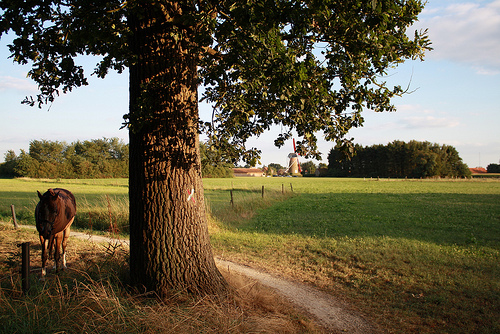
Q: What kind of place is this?
A: It is a field.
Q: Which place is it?
A: It is a field.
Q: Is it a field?
A: Yes, it is a field.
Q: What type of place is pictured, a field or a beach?
A: It is a field.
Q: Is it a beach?
A: No, it is a field.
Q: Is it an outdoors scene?
A: Yes, it is outdoors.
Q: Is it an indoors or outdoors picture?
A: It is outdoors.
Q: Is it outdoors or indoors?
A: It is outdoors.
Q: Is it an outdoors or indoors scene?
A: It is outdoors.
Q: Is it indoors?
A: No, it is outdoors.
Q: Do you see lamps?
A: No, there are no lamps.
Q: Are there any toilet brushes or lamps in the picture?
A: No, there are no lamps or toilet brushes.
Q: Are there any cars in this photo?
A: No, there are no cars.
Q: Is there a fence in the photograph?
A: Yes, there is a fence.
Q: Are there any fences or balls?
A: Yes, there is a fence.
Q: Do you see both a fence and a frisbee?
A: No, there is a fence but no frisbees.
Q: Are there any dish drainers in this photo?
A: No, there are no dish drainers.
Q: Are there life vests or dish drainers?
A: No, there are no dish drainers or life vests.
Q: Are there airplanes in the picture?
A: No, there are no airplanes.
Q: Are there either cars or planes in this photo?
A: No, there are no planes or cars.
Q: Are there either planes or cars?
A: No, there are no planes or cars.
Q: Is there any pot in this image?
A: No, there are no pots.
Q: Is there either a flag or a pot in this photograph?
A: No, there are no pots or flags.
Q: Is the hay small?
A: Yes, the hay is small.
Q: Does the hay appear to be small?
A: Yes, the hay is small.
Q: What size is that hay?
A: The hay is small.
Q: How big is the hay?
A: The hay is small.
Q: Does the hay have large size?
A: No, the hay is small.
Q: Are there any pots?
A: No, there are no pots.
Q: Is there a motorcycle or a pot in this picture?
A: No, there are no pots or motorcycles.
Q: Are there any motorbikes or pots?
A: No, there are no pots or motorbikes.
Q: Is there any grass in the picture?
A: Yes, there is grass.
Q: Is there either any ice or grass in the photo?
A: Yes, there is grass.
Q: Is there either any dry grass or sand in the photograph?
A: Yes, there is dry grass.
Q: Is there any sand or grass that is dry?
A: Yes, the grass is dry.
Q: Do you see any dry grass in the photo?
A: Yes, there is dry grass.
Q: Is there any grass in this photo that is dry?
A: Yes, there is grass that is dry.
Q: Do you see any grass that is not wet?
A: Yes, there is dry grass.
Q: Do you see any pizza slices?
A: No, there are no pizza slices.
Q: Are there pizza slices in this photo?
A: No, there are no pizza slices.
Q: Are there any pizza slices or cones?
A: No, there are no pizza slices or cones.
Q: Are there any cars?
A: No, there are no cars.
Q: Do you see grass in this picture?
A: Yes, there is grass.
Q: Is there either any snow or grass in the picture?
A: Yes, there is grass.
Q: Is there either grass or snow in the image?
A: Yes, there is grass.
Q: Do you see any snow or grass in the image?
A: Yes, there is grass.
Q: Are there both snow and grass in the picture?
A: No, there is grass but no snow.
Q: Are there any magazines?
A: No, there are no magazines.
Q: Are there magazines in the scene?
A: No, there are no magazines.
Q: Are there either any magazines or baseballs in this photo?
A: No, there are no magazines or baseballs.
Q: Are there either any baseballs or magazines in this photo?
A: No, there are no magazines or baseballs.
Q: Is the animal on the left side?
A: Yes, the animal is on the left of the image.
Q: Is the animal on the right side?
A: No, the animal is on the left of the image.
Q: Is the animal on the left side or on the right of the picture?
A: The animal is on the left of the image.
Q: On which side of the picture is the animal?
A: The animal is on the left of the image.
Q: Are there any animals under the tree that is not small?
A: Yes, there is an animal under the tree.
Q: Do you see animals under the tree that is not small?
A: Yes, there is an animal under the tree.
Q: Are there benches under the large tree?
A: No, there is an animal under the tree.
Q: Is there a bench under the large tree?
A: No, there is an animal under the tree.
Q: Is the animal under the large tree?
A: Yes, the animal is under the tree.